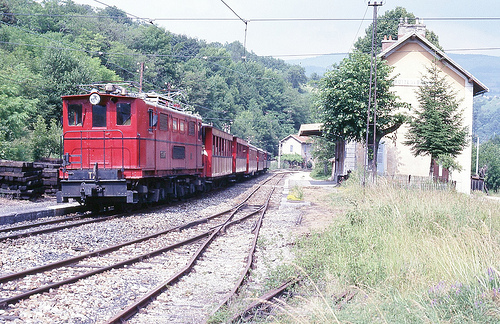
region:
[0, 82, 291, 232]
long red train on tracks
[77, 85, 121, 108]
front light on train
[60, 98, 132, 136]
windows on train front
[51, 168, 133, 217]
safety ram on train front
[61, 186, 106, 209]
cable car hook up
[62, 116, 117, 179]
railings on front of train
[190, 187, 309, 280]
metal train tracks on road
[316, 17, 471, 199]
small white house by tracks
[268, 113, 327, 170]
small white house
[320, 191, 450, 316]
overgrown grass by tracks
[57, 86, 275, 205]
a red train in a rural setting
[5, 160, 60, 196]
stacks of railroad ties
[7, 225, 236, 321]
several sets of train tracks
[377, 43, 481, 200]
a small yellow home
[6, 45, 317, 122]
tons of green trees behind the train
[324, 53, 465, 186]
two small trees by the house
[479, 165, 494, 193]
a person behind the house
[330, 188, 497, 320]
the grass is growing tall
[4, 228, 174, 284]
gravel is on the ground where the tracks lay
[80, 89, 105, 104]
the train has a light on it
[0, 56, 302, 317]
a red train on a railroad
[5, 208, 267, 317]
railroad filled with gravel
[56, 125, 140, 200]
a metal gate in front a train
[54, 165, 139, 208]
bumper of train is black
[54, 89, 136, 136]
three windows in front a train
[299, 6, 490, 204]
trees in front a house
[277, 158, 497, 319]
grass on side railroad is long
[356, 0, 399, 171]
a pole in front a house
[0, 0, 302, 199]
green trees on left side of train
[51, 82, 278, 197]
cars of train are red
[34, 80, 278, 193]
Red train traveling through mountains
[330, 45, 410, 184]
green tree on building side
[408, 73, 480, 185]
green tree on building side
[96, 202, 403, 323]
Second set of railroad tracks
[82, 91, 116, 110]
Round headlight on front of train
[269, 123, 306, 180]
Small white building in background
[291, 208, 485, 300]
Tall grass on side of tracks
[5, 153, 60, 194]
Wood pallets stacked by train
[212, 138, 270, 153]
Windows on side of train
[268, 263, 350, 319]
Rails leading off into overgrown grass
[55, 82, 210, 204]
red caboose at the end of a line of red train cars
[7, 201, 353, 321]
train tracks at an old train station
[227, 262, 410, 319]
train tracks disappearing into tall grass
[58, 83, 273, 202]
shiny red train cars with black trim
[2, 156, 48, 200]
stacks of wooden ties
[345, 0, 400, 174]
telephone pole towering high above train depot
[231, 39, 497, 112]
mountains in distance beyond train station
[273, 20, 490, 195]
old abandoned appearing train station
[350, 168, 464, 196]
old wooden fence alongside train station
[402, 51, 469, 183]
stately evergreen tree beside train depot